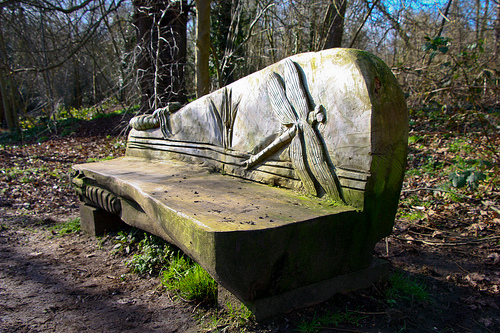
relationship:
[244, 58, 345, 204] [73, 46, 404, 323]
dragonfly on bench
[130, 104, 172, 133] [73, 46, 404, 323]
bug on bench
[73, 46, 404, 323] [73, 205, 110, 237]
bench has leg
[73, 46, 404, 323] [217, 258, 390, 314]
bench has leg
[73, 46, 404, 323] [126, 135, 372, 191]
bench has grooves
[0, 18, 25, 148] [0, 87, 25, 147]
tree has trunk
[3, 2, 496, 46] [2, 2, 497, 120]
sky behind trees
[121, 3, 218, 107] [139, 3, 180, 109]
tree has branches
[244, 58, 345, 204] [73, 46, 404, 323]
dragonfly ong bench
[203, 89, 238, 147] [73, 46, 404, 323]
cattails are on bench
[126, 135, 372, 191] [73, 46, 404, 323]
lines are on bench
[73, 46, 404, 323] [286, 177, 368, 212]
bench has moss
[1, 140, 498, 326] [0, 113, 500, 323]
mud on ground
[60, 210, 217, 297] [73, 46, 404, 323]
grass+weeds are beneath bench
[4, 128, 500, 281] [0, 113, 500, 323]
leaves are on ground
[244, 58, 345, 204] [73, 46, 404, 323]
dragonfly on rock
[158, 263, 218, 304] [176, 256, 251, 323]
grass on rock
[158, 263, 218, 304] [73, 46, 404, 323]
grass near bench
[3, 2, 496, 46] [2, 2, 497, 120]
sky through trees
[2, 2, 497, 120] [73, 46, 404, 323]
trees are behind bench